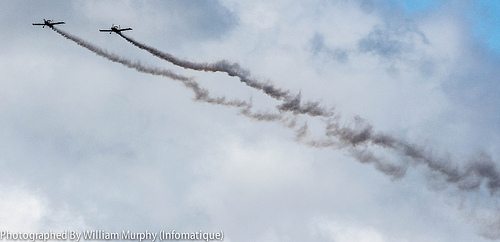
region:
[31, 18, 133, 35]
two older planes are flying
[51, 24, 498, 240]
planes leave smoky jet trail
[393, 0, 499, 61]
blue spot in the sky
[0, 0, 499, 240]
sky is cloudy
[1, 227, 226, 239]
white tag at bottom of image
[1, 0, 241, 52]
dark cloud spot at top left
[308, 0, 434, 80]
wispy cloud at top right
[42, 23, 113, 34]
planes have wheels out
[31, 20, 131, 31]
planes have wings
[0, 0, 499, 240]
sky is stormy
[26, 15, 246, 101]
There are 2 planes in the sky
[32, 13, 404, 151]
The planes are smoking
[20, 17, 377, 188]
The sky is cloudy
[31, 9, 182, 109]
The planes have 1 engine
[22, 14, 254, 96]
The planes have 4 wings altogether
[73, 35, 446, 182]
The smoke is grey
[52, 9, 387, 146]
This was taken during the day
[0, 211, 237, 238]
This is the photographer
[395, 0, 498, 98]
The sky is blue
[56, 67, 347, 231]
The clouds are white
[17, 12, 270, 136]
two dark vapor trails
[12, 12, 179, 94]
two stunt planes together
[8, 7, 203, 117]
two planes in a dogfight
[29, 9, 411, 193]
planes in a cloudy sky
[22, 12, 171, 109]
two propeller planes in flight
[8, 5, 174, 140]
small planes with non-retractable landing gear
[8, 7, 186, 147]
Piper Cubs flying together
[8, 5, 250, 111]
two planes hit by missiles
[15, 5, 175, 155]
a neck and neck plane race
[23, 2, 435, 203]
two planes in a steep climb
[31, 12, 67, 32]
airplane with black trail of smoke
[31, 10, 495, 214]
two small planes with smoke trails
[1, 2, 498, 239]
blue sky with clouds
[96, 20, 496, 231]
smoke trails are dissapating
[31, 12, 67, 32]
airplane has wheels underneath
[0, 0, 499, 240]
clouds are white and grey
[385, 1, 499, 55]
small area of sky showing through clouds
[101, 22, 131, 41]
small plane behind other small plane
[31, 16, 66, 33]
small plane in front of other small plane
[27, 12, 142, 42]
two small planes flying near each other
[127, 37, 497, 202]
the smoke is black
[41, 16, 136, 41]
the planes are in the air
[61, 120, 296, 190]
the sky is cloudy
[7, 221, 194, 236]
the text is white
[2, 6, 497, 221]
the clouds are dark grey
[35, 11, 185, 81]
the planes are two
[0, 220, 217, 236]
the photographer was taken by william murphy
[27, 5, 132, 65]
the plane has legs down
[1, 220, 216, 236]
the words are at the bottom of the photo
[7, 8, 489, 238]
the photo was taken during the day